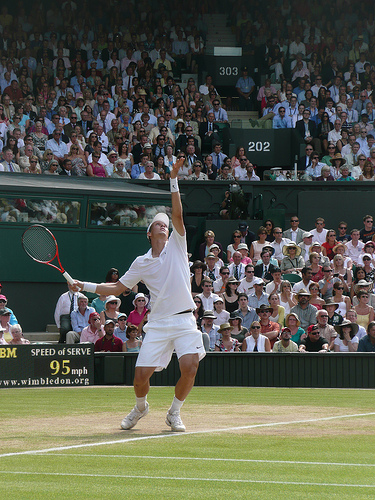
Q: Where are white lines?
A: On the court.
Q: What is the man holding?
A: Tennis racket.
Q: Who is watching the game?
A: Spectators.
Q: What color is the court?
A: Green.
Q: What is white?
A: Player's visor.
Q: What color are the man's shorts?
A: White.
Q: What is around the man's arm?
A: Arm band.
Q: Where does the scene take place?
A: At a tennis game.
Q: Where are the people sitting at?
A: In the stands.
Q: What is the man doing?
A: Attempting to hit a tennis ball.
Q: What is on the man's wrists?
A: Wristband.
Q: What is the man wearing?
A: A shirt and shorts.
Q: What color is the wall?
A: Green.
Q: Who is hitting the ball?
A: Tennis player.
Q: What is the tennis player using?
A: Tennis racket.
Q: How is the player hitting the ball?
A: By throwing ball in air.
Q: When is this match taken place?
A: Daytime.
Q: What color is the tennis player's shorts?
A: White.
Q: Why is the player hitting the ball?
A: To serve ball to opponent.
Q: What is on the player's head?
A: Cap.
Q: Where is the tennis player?
A: Tennis court.